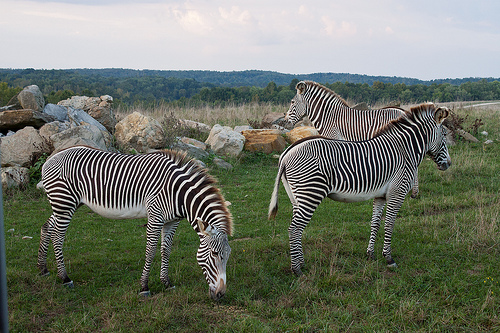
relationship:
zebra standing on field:
[35, 144, 234, 301] [426, 233, 488, 320]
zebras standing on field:
[277, 80, 414, 151] [426, 233, 488, 320]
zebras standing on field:
[270, 103, 463, 273] [426, 233, 488, 320]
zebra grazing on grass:
[35, 144, 234, 301] [1, 110, 498, 328]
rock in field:
[3, 118, 44, 195] [16, 158, 491, 322]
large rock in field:
[39, 113, 114, 148] [4, 68, 480, 316]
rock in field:
[167, 134, 205, 155] [1, 103, 497, 330]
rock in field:
[206, 114, 245, 166] [3, 147, 495, 329]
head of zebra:
[401, 102, 461, 172] [25, 142, 246, 294]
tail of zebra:
[262, 151, 298, 227] [265, 96, 464, 281]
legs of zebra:
[274, 196, 413, 272] [277, 103, 453, 280]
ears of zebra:
[426, 102, 450, 123] [265, 96, 464, 281]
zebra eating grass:
[25, 142, 246, 294] [2, 148, 492, 331]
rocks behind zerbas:
[6, 104, 271, 154] [35, 147, 245, 301]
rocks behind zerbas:
[6, 104, 271, 154] [268, 98, 461, 273]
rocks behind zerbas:
[6, 104, 271, 154] [285, 75, 402, 135]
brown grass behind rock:
[119, 103, 285, 126] [113, 110, 318, 170]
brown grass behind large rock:
[119, 103, 285, 126] [0, 122, 51, 168]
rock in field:
[115, 110, 165, 152] [13, 32, 498, 326]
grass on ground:
[376, 233, 426, 280] [5, 101, 494, 331]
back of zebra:
[311, 130, 399, 158] [265, 96, 464, 281]